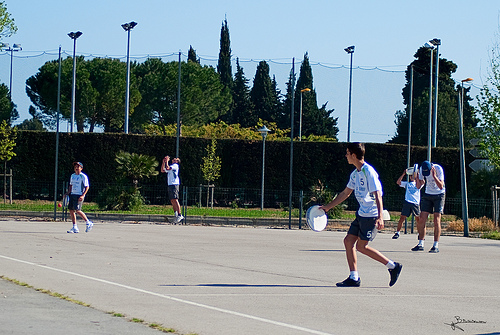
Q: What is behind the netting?
A: Trees.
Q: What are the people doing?
A: Playing frisbee.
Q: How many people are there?
A: 5.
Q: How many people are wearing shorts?
A: 5.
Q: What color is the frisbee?
A: White.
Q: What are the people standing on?
A: Paved court.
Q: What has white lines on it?
A: The court.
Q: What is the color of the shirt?
A: White.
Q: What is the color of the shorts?
A: Black.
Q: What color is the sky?
A: Blue.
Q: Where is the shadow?
A: In the ground.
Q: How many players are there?
A: 5.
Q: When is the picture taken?
A: Daytime.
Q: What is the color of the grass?
A: Green.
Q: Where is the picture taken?
A: At a park.